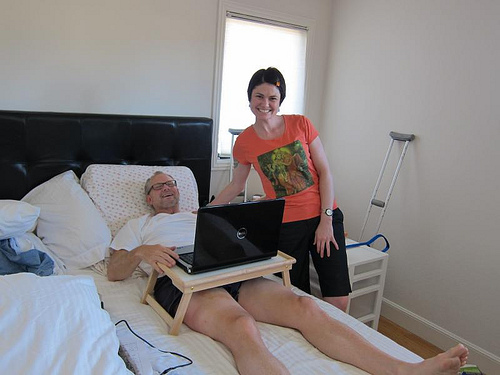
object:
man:
[107, 171, 471, 375]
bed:
[0, 108, 427, 375]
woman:
[191, 67, 353, 314]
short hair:
[247, 66, 286, 106]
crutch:
[357, 131, 415, 248]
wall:
[336, 39, 500, 168]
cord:
[98, 300, 193, 374]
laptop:
[169, 199, 286, 274]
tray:
[141, 251, 297, 337]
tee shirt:
[108, 212, 197, 280]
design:
[257, 140, 314, 200]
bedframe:
[0, 109, 213, 209]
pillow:
[0, 165, 203, 276]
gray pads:
[389, 130, 415, 141]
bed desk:
[140, 250, 295, 336]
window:
[208, 5, 311, 173]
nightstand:
[308, 229, 388, 332]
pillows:
[18, 170, 111, 273]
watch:
[320, 208, 334, 217]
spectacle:
[345, 234, 390, 252]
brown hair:
[247, 67, 285, 108]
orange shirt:
[233, 114, 338, 223]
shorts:
[272, 207, 353, 297]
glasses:
[147, 180, 177, 195]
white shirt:
[109, 211, 198, 279]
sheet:
[61, 264, 435, 375]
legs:
[165, 270, 469, 374]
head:
[144, 171, 180, 213]